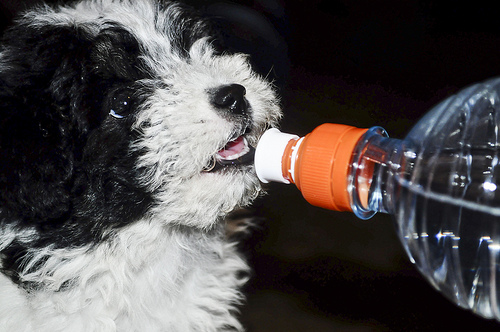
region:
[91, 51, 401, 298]
a dog is drinking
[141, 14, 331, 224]
a dog is drinking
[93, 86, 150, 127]
eye of the dog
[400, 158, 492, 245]
plastic water bottle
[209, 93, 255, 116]
nose of the dog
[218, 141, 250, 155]
the dogs pink tongue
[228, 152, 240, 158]
the dogs white teeth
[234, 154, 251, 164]
lips of the dog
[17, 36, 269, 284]
dog is black and white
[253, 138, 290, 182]
top of the water bottle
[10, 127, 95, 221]
the dogs ear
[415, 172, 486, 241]
water in the bottle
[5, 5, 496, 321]
dog about to drink from a bottle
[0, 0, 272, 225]
face of a small black and white dog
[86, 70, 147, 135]
right eye of a dog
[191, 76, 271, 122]
dog's nose surrounded by white fur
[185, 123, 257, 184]
a dog's open mouth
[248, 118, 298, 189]
white cap of a water bottle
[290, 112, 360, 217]
orange screw top of a water bottle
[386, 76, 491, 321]
top of a clear plastic bottle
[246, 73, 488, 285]
water bottle with an orange and white top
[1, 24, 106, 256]
dog's ear with black fur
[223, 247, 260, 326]
fur on dog's chest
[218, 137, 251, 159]
tongue in the dog's mouth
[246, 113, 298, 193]
nozzle of the water bottle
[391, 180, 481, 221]
water in the bottle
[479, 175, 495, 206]
light on the water bottle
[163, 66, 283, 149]
muzzle of the dog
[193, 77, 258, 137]
nose on the dog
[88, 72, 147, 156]
eye of the dog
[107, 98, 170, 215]
fur on the dog's face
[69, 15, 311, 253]
dog drinking from water bottle